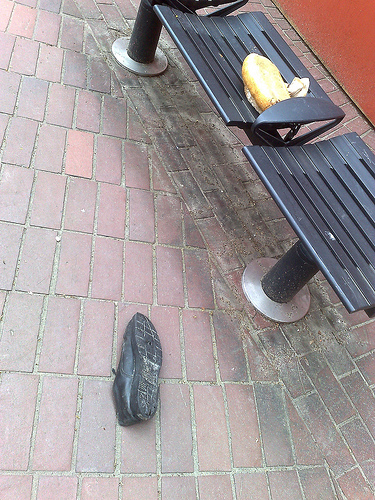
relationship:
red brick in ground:
[52, 122, 116, 183] [37, 149, 225, 347]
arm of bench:
[253, 93, 347, 141] [118, 5, 373, 320]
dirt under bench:
[199, 244, 284, 338] [151, 0, 358, 329]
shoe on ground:
[80, 274, 219, 443] [37, 105, 171, 240]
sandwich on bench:
[239, 51, 289, 116] [153, 4, 344, 125]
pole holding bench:
[261, 237, 321, 303] [118, 5, 373, 320]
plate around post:
[218, 254, 333, 334] [246, 239, 326, 330]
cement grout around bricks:
[33, 464, 322, 476] [0, 368, 296, 468]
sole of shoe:
[134, 325, 155, 403] [109, 313, 160, 427]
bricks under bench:
[162, 109, 228, 207] [118, 5, 373, 320]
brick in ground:
[189, 379, 234, 474] [0, 1, 373, 499]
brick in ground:
[30, 375, 81, 472] [0, 1, 373, 499]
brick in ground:
[75, 297, 119, 376] [0, 1, 373, 499]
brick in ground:
[86, 235, 124, 299] [0, 1, 373, 499]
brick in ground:
[154, 245, 183, 309] [0, 1, 373, 499]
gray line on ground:
[182, 380, 208, 478] [233, 461, 281, 489]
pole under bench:
[261, 237, 321, 303] [118, 5, 373, 320]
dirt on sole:
[141, 354, 159, 370] [133, 310, 162, 418]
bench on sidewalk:
[241, 130, 373, 323] [0, 0, 373, 497]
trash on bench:
[236, 51, 313, 115] [118, 5, 373, 320]